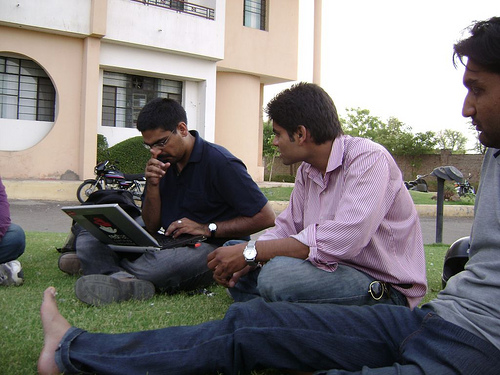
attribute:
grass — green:
[7, 282, 213, 323]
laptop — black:
[57, 200, 199, 257]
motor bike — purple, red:
[73, 157, 145, 202]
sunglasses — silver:
[139, 138, 174, 152]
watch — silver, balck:
[241, 235, 262, 265]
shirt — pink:
[246, 140, 430, 297]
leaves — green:
[356, 109, 467, 158]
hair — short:
[129, 91, 191, 139]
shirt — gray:
[436, 150, 499, 326]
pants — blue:
[60, 304, 491, 374]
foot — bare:
[25, 280, 80, 372]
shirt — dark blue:
[143, 147, 269, 239]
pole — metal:
[309, 0, 330, 87]